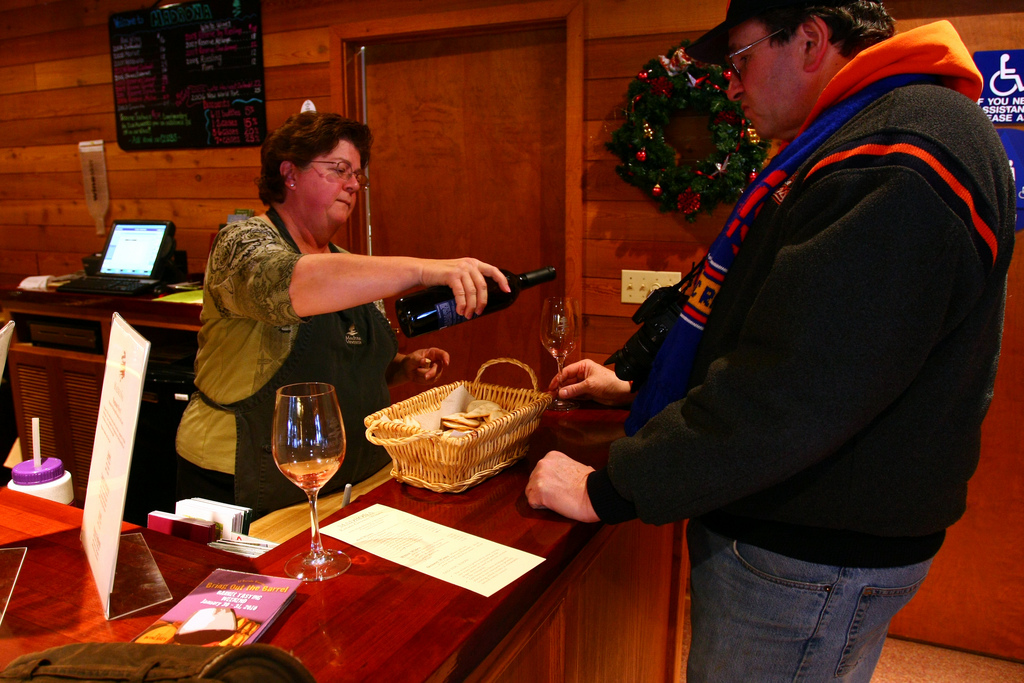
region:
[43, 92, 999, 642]
this is a cafe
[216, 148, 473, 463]
the woman is pouring wine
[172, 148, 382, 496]
the woman has an apron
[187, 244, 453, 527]
the apron is black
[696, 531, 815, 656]
the mans jeans are light blue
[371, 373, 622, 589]
this is a wicker basket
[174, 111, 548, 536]
woman standing behind the bar pouring a drink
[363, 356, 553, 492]
wicker basket with crackers in it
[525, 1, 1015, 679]
man standing at the bar waiting for his glass of wine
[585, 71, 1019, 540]
black jacket man is wearing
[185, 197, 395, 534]
black apron woman is wearing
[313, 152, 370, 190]
eyeglasses woman is wearing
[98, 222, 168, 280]
monitor screen of computer in the distance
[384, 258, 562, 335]
bottle of wine woman is pouring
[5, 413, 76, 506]
plastic drinking cup with a straw in it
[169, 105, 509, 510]
female waiter wearing a green apron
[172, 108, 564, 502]
woman pouring wine into a stem glass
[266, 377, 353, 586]
empty wine glass on top of the counter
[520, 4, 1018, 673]
man standing behind the counter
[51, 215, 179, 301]
black laptop computer on the table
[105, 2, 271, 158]
menu attached to the wall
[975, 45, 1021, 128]
blue and white handicap sign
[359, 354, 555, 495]
wooden basket with cookies inside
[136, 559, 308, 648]
pamphlet on the counter beside the wine glass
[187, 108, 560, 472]
woman pouring wine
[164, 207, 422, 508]
dark green apron woman is wearing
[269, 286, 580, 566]
wine glasses on the bar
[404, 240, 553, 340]
wine bottle woman is holding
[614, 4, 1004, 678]
man standing at bar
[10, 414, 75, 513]
purple and white bottle with straw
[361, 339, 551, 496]
basket on the bar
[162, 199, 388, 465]
green shirt woman is wearing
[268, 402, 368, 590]
wine glass on the counter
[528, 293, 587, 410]
man holding a wine glass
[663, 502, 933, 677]
man wearing blue jeans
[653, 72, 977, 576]
man wearing a black jacket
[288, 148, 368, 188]
woman wearing reading glasses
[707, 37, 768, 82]
man wearing reading glasses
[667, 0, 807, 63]
man wearing a black hat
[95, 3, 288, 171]
sign on the wall with a menu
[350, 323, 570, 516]
wick basket on the counter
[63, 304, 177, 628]
menu on the counter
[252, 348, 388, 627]
this is a glass of wine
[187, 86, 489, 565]
she is pouring wine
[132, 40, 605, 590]
she is pouring wine into a glass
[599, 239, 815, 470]
this is a camera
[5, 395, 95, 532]
this is a water bottle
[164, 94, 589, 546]
the woman is wearing an apron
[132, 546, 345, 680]
this is a menu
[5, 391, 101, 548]
the bottle has a purple lid